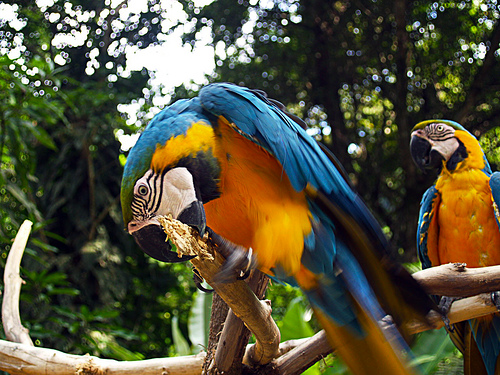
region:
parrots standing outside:
[49, 43, 495, 341]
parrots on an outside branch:
[82, 59, 499, 319]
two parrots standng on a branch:
[74, 32, 477, 374]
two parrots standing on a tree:
[87, 41, 494, 319]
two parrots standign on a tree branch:
[115, 41, 475, 359]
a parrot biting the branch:
[112, 71, 389, 374]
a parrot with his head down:
[97, 58, 440, 354]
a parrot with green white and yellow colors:
[35, 61, 431, 343]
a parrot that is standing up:
[389, 93, 492, 300]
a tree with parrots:
[39, 21, 481, 373]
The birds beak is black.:
[130, 224, 199, 269]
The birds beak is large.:
[131, 221, 202, 262]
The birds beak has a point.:
[127, 224, 196, 266]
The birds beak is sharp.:
[133, 223, 198, 268]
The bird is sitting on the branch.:
[406, 111, 496, 273]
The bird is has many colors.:
[401, 112, 497, 374]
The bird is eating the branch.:
[122, 96, 257, 286]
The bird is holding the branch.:
[126, 104, 256, 294]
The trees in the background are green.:
[299, 2, 498, 79]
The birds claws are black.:
[433, 294, 498, 335]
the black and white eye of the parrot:
[137, 182, 147, 194]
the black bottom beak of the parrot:
[179, 200, 206, 228]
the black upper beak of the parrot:
[136, 225, 197, 263]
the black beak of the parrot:
[409, 133, 430, 164]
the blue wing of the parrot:
[202, 82, 423, 314]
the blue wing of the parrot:
[413, 186, 441, 266]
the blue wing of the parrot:
[487, 168, 498, 205]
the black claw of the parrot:
[186, 235, 251, 292]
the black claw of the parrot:
[437, 292, 456, 314]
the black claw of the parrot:
[485, 288, 498, 305]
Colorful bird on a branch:
[393, 81, 499, 331]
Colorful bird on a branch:
[76, 67, 376, 374]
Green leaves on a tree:
[428, 3, 495, 63]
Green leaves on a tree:
[445, 63, 496, 116]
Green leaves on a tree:
[473, 111, 499, 163]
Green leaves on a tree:
[367, 7, 412, 54]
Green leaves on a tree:
[5, 10, 90, 82]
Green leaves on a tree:
[17, 76, 89, 126]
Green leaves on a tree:
[10, 141, 92, 219]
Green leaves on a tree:
[36, 271, 153, 340]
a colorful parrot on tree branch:
[117, 91, 439, 341]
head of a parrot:
[107, 117, 219, 270]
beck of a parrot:
[111, 197, 222, 264]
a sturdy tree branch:
[4, 222, 46, 357]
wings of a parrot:
[199, 80, 444, 322]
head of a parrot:
[400, 113, 492, 173]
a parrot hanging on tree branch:
[396, 118, 498, 373]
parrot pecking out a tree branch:
[104, 72, 429, 362]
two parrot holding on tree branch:
[46, 72, 497, 366]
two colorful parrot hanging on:
[102, 72, 494, 367]